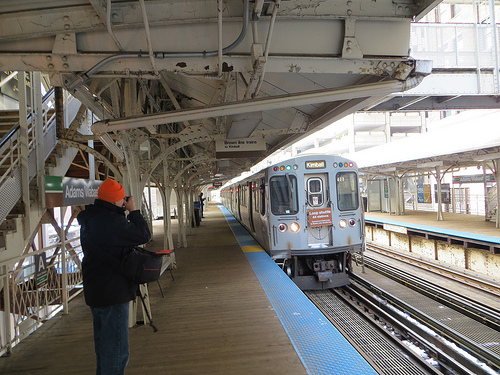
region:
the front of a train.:
[255, 156, 365, 277]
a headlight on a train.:
[283, 218, 305, 235]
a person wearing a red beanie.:
[81, 172, 175, 374]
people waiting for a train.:
[176, 184, 217, 228]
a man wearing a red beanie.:
[93, 170, 138, 206]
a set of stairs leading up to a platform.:
[9, 57, 99, 287]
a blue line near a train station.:
[212, 199, 375, 372]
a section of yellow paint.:
[232, 236, 268, 263]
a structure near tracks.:
[350, 146, 498, 229]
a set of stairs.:
[5, 83, 106, 285]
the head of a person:
[90, 172, 131, 212]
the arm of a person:
[110, 207, 150, 247]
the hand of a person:
[119, 188, 144, 214]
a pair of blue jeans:
[86, 297, 141, 373]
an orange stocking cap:
[92, 173, 128, 204]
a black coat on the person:
[66, 196, 156, 309]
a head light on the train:
[287, 217, 303, 235]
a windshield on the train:
[268, 171, 302, 222]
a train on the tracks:
[213, 150, 372, 302]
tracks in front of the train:
[303, 270, 435, 374]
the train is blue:
[228, 97, 377, 274]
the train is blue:
[239, 147, 390, 368]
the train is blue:
[202, 58, 333, 248]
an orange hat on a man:
[96, 174, 129, 207]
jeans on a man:
[86, 299, 136, 373]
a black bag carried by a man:
[117, 240, 166, 287]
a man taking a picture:
[81, 173, 155, 373]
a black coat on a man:
[77, 204, 150, 300]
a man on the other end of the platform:
[197, 187, 206, 218]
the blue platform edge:
[220, 202, 367, 373]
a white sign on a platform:
[206, 131, 276, 161]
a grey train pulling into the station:
[209, 155, 367, 287]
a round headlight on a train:
[289, 219, 300, 233]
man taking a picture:
[31, 148, 213, 370]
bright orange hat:
[66, 164, 161, 234]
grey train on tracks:
[205, 130, 384, 304]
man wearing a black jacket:
[17, 150, 178, 341]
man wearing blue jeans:
[61, 176, 208, 361]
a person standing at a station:
[177, 169, 219, 236]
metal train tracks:
[327, 219, 485, 370]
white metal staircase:
[1, 61, 91, 298]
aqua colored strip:
[216, 210, 356, 361]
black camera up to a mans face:
[114, 182, 147, 214]